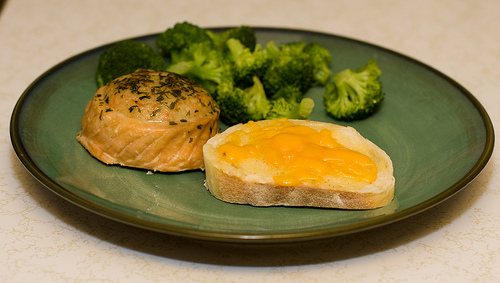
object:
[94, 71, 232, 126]
specks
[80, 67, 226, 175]
food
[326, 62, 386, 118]
broccoli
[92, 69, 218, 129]
herbs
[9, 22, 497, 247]
plate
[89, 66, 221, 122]
seasoning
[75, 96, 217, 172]
meat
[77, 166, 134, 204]
shadow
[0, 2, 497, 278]
counter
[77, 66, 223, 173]
fish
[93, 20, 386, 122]
broccoli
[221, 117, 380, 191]
cheese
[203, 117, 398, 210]
bread